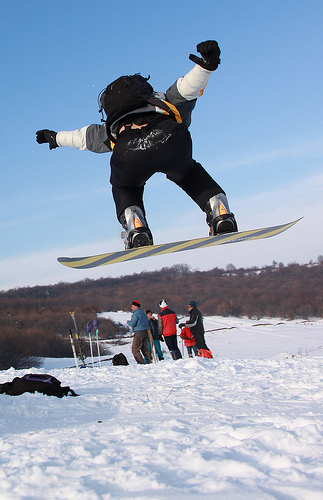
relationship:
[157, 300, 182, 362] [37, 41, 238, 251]
person below snow boarder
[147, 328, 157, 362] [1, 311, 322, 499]
ski sticking out of ground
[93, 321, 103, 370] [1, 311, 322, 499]
pole sticking out of ground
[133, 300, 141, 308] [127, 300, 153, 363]
cap on person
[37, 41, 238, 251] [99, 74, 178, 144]
snow boarder has back pack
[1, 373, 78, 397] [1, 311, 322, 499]
bag laying on ground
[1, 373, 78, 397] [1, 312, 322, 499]
bag in snow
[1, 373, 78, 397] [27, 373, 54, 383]
bag has stripes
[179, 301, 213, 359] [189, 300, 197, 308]
person has cap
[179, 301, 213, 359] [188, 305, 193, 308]
person has goggles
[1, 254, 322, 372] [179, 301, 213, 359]
woods behind person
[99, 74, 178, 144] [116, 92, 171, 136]
back pack on back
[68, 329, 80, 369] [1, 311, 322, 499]
pole in ground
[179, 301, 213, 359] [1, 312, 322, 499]
person in snow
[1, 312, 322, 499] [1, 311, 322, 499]
snow on ground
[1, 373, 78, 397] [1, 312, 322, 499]
bag lies in snow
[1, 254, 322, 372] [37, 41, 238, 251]
woods behind snow boarder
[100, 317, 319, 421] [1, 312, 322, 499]
tracks in snow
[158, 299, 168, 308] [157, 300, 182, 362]
cap on person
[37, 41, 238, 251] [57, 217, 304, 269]
snow boarder on snowboard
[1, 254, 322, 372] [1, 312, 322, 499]
woods behind snow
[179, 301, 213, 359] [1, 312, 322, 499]
person standing on snow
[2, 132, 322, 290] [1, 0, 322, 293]
clouds in sky